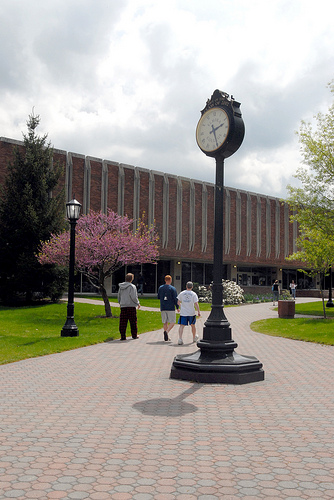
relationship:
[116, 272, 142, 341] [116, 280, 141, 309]
guy wearing grey jacket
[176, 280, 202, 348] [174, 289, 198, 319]
boy wearing shirt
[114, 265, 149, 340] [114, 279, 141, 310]
guy in grey jacket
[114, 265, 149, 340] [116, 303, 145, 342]
guy in pants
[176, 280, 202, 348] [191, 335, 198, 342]
boy wearing sneaker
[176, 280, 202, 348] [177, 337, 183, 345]
boy wearing sneaker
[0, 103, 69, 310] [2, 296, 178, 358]
tree on grass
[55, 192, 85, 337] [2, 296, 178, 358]
lamp post on grass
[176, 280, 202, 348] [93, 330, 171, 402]
boy on sidewalk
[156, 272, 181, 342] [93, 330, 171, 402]
guy on sidewalk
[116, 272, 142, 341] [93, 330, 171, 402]
guy on sidewalk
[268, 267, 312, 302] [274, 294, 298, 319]
women behind receptacle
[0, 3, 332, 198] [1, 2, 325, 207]
clouds covering sky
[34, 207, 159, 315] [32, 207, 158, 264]
tree with blossoms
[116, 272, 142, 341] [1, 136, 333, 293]
guy walking towards building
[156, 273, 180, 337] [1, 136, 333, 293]
guy walking towards building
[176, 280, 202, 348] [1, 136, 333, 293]
boy walking towards building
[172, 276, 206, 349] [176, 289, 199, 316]
boy wearing shirt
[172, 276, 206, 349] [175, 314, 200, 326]
boy wearing shorts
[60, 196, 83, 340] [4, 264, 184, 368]
street light in grass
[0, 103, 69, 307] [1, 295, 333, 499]
tree on campus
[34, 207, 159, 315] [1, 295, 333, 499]
tree on campus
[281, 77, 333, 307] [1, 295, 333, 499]
tree on campus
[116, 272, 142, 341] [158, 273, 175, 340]
guy walking next to a person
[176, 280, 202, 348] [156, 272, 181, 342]
boy walking next to a guy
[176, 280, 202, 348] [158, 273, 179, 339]
boy walking next to a person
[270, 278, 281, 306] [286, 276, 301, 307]
women walking in front of person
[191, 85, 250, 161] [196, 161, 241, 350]
clock over pole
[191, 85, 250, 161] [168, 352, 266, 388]
clock over foundation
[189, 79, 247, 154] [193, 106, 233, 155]
ornamentation on clock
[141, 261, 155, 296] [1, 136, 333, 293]
window on building